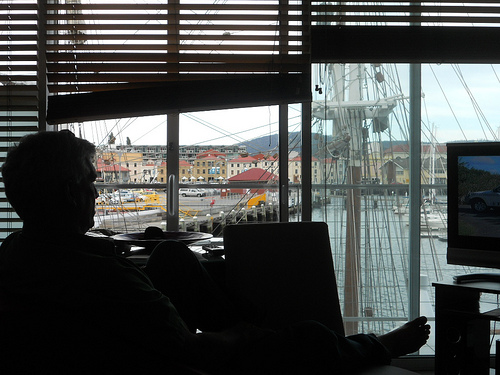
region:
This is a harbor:
[172, 112, 488, 320]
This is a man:
[13, 131, 181, 355]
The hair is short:
[23, 136, 75, 204]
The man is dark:
[12, 122, 122, 338]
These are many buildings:
[105, 95, 350, 227]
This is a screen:
[377, 157, 492, 228]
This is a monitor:
[372, 151, 495, 296]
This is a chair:
[235, 237, 312, 297]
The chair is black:
[140, 170, 290, 318]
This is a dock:
[163, 138, 270, 280]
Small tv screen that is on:
[438, 118, 498, 277]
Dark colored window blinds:
[310, 2, 499, 65]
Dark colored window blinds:
[36, 1, 312, 121]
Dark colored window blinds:
[0, 4, 45, 240]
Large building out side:
[227, 142, 362, 203]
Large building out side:
[187, 137, 239, 200]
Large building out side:
[100, 140, 165, 200]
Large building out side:
[374, 125, 472, 207]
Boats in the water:
[393, 196, 451, 254]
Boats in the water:
[426, 212, 451, 252]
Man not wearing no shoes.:
[363, 315, 456, 371]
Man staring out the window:
[31, 126, 231, 342]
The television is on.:
[423, 137, 496, 284]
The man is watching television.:
[8, 139, 142, 341]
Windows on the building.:
[182, 160, 255, 179]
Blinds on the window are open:
[41, 38, 279, 127]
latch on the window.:
[153, 155, 188, 222]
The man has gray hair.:
[24, 120, 82, 188]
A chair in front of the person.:
[209, 198, 347, 306]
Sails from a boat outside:
[316, 73, 423, 292]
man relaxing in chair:
[22, 143, 428, 347]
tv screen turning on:
[437, 144, 489, 281]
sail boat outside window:
[315, 84, 430, 311]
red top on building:
[232, 169, 287, 206]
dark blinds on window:
[57, 36, 322, 118]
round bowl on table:
[129, 217, 203, 248]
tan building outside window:
[193, 154, 235, 186]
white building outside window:
[229, 152, 266, 173]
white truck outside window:
[147, 182, 296, 212]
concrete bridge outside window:
[169, 205, 254, 220]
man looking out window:
[11, 127, 105, 244]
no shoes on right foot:
[367, 313, 432, 363]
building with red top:
[229, 170, 281, 210]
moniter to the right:
[449, 148, 499, 270]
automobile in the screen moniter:
[456, 165, 499, 221]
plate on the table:
[116, 216, 199, 253]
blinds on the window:
[2, 75, 38, 156]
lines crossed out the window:
[92, 123, 268, 189]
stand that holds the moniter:
[433, 288, 498, 374]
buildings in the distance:
[99, 147, 252, 182]